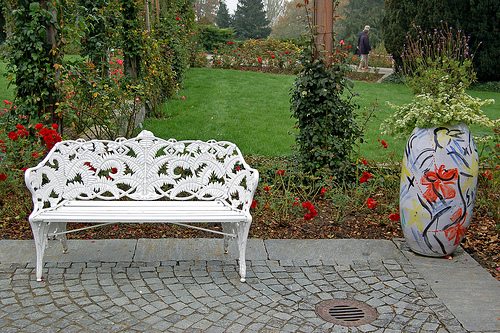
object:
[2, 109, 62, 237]
bush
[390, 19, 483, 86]
flowers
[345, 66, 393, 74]
walkway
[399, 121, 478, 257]
flower pot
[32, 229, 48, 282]
left foot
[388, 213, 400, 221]
flowers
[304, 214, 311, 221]
flowers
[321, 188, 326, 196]
flowers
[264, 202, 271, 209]
flowers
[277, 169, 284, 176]
flowers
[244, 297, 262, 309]
bricks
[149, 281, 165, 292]
bricks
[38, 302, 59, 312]
bricks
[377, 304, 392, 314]
bricks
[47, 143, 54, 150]
flowers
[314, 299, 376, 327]
drainage hole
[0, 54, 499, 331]
ground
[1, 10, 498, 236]
garden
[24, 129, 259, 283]
bench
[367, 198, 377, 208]
flower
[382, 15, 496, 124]
plant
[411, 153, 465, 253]
print